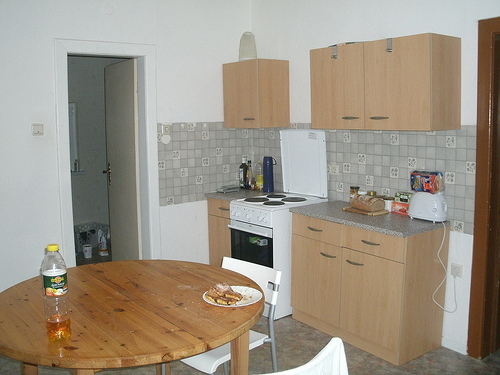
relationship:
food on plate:
[204, 286, 244, 304] [206, 276, 264, 315]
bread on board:
[348, 192, 385, 210] [345, 206, 390, 218]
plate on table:
[206, 276, 264, 315] [15, 256, 261, 371]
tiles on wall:
[158, 126, 226, 188] [10, 22, 59, 240]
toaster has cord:
[407, 191, 453, 223] [435, 228, 463, 313]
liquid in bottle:
[42, 315, 71, 337] [37, 240, 79, 339]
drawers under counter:
[293, 217, 406, 254] [345, 215, 424, 239]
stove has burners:
[228, 190, 295, 258] [242, 188, 308, 207]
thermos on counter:
[256, 155, 280, 194] [213, 183, 264, 201]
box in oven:
[247, 235, 271, 248] [228, 190, 295, 258]